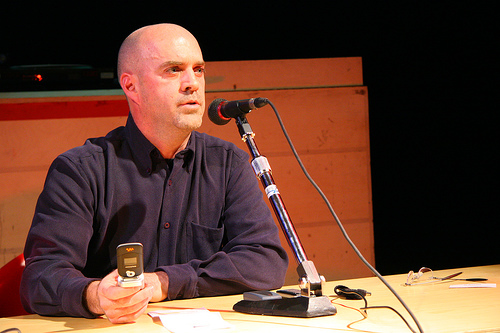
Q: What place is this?
A: It is a stage.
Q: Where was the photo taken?
A: It was taken at the stage.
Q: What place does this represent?
A: It represents the stage.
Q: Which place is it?
A: It is a stage.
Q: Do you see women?
A: No, there are no women.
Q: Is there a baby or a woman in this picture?
A: No, there are no women or babies.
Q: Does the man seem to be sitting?
A: Yes, the man is sitting.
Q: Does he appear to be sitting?
A: Yes, the man is sitting.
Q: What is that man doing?
A: The man is sitting.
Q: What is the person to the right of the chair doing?
A: The man is sitting.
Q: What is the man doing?
A: The man is sitting.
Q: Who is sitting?
A: The man is sitting.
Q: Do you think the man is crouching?
A: No, the man is sitting.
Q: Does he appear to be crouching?
A: No, the man is sitting.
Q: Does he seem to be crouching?
A: No, the man is sitting.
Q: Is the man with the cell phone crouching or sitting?
A: The man is sitting.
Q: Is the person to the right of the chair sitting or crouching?
A: The man is sitting.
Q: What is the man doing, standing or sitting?
A: The man is sitting.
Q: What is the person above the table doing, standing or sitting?
A: The man is sitting.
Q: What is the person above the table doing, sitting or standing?
A: The man is sitting.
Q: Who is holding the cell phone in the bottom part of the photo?
A: The man is holding the cell phone.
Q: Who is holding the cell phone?
A: The man is holding the cell phone.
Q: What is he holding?
A: The man is holding the mobile phone.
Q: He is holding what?
A: The man is holding the mobile phone.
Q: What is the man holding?
A: The man is holding the mobile phone.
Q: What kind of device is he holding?
A: The man is holding the mobile phone.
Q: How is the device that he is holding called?
A: The device is a cell phone.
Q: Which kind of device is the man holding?
A: The man is holding the mobile phone.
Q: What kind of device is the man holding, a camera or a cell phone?
A: The man is holding a cell phone.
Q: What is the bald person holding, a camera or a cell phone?
A: The man is holding a cell phone.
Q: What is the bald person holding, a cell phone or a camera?
A: The man is holding a cell phone.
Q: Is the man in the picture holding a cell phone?
A: Yes, the man is holding a cell phone.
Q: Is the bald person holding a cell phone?
A: Yes, the man is holding a cell phone.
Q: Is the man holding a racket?
A: No, the man is holding a cell phone.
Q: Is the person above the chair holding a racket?
A: No, the man is holding a cell phone.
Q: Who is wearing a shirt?
A: The man is wearing a shirt.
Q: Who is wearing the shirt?
A: The man is wearing a shirt.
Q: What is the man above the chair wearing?
A: The man is wearing a shirt.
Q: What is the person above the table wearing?
A: The man is wearing a shirt.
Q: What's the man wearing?
A: The man is wearing a shirt.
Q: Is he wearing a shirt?
A: Yes, the man is wearing a shirt.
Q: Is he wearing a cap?
A: No, the man is wearing a shirt.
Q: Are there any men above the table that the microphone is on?
A: Yes, there is a man above the table.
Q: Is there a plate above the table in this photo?
A: No, there is a man above the table.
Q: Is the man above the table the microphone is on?
A: Yes, the man is above the table.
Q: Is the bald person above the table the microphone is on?
A: Yes, the man is above the table.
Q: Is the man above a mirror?
A: No, the man is above the table.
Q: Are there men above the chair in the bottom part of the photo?
A: Yes, there is a man above the chair.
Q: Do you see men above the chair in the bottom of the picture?
A: Yes, there is a man above the chair.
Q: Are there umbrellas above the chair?
A: No, there is a man above the chair.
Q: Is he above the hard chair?
A: Yes, the man is above the chair.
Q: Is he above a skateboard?
A: No, the man is above the chair.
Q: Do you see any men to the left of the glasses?
A: Yes, there is a man to the left of the glasses.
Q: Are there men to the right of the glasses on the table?
A: No, the man is to the left of the glasses.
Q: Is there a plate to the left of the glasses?
A: No, there is a man to the left of the glasses.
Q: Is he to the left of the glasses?
A: Yes, the man is to the left of the glasses.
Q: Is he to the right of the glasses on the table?
A: No, the man is to the left of the glasses.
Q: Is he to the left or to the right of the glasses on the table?
A: The man is to the left of the glasses.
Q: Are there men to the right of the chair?
A: Yes, there is a man to the right of the chair.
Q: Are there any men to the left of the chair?
A: No, the man is to the right of the chair.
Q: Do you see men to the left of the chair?
A: No, the man is to the right of the chair.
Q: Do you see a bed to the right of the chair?
A: No, there is a man to the right of the chair.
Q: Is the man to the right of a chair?
A: Yes, the man is to the right of a chair.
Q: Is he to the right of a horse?
A: No, the man is to the right of a chair.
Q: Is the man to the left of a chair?
A: No, the man is to the right of a chair.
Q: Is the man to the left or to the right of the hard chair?
A: The man is to the right of the chair.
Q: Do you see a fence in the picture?
A: No, there are no fences.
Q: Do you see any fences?
A: No, there are no fences.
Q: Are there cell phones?
A: Yes, there is a cell phone.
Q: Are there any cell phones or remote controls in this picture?
A: Yes, there is a cell phone.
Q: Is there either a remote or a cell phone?
A: Yes, there is a cell phone.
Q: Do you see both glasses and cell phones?
A: Yes, there are both a cell phone and glasses.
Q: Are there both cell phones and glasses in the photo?
A: Yes, there are both a cell phone and glasses.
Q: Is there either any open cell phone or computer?
A: Yes, there is an open cell phone.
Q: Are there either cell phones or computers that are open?
A: Yes, the cell phone is open.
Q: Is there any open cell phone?
A: Yes, there is an open cell phone.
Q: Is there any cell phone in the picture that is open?
A: Yes, there is a cell phone that is open.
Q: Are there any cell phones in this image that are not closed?
A: Yes, there is a open cell phone.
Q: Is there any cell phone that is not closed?
A: Yes, there is a open cell phone.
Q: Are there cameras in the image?
A: No, there are no cameras.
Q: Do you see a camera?
A: No, there are no cameras.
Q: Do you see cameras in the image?
A: No, there are no cameras.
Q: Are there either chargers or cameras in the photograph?
A: No, there are no cameras or chargers.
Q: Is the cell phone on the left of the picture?
A: Yes, the cell phone is on the left of the image.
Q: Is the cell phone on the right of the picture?
A: No, the cell phone is on the left of the image.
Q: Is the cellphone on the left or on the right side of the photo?
A: The cellphone is on the left of the image.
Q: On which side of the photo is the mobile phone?
A: The mobile phone is on the left of the image.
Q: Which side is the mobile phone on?
A: The mobile phone is on the left of the image.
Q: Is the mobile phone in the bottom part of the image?
A: Yes, the mobile phone is in the bottom of the image.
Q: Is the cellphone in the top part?
A: No, the cellphone is in the bottom of the image.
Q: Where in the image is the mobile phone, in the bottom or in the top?
A: The mobile phone is in the bottom of the image.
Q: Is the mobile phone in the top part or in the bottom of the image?
A: The mobile phone is in the bottom of the image.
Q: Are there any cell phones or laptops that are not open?
A: No, there is a cell phone but it is open.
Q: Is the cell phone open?
A: Yes, the cell phone is open.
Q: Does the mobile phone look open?
A: Yes, the mobile phone is open.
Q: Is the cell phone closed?
A: No, the cell phone is open.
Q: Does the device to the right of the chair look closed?
A: No, the mobile phone is open.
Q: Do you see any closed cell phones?
A: No, there is a cell phone but it is open.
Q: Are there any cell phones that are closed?
A: No, there is a cell phone but it is open.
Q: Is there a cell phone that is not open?
A: No, there is a cell phone but it is open.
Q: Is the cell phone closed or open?
A: The cell phone is open.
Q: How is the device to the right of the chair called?
A: The device is a cell phone.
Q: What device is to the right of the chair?
A: The device is a cell phone.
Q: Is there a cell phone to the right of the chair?
A: Yes, there is a cell phone to the right of the chair.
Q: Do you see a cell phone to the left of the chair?
A: No, the cell phone is to the right of the chair.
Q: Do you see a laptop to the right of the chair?
A: No, there is a cell phone to the right of the chair.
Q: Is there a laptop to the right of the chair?
A: No, there is a cell phone to the right of the chair.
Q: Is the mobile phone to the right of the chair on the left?
A: Yes, the mobile phone is to the right of the chair.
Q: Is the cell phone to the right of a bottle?
A: No, the cell phone is to the right of the chair.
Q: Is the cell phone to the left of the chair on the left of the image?
A: No, the cell phone is to the right of the chair.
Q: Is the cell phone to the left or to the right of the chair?
A: The cell phone is to the right of the chair.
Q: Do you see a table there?
A: Yes, there is a table.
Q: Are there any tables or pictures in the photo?
A: Yes, there is a table.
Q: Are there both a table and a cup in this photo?
A: No, there is a table but no cups.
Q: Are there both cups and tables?
A: No, there is a table but no cups.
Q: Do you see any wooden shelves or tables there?
A: Yes, there is a wood table.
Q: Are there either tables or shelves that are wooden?
A: Yes, the table is wooden.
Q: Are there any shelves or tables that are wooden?
A: Yes, the table is wooden.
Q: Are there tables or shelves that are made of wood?
A: Yes, the table is made of wood.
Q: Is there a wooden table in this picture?
A: Yes, there is a wood table.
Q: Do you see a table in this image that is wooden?
A: Yes, there is a table that is wooden.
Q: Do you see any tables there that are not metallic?
A: Yes, there is a wooden table.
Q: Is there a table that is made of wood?
A: Yes, there is a table that is made of wood.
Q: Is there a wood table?
A: Yes, there is a table that is made of wood.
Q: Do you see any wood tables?
A: Yes, there is a table that is made of wood.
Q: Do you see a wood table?
A: Yes, there is a table that is made of wood.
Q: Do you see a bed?
A: No, there are no beds.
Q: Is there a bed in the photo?
A: No, there are no beds.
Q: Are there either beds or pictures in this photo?
A: No, there are no beds or pictures.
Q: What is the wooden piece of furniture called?
A: The piece of furniture is a table.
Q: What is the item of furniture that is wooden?
A: The piece of furniture is a table.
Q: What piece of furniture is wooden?
A: The piece of furniture is a table.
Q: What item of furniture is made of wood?
A: The piece of furniture is a table.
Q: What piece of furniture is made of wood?
A: The piece of furniture is a table.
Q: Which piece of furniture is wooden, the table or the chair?
A: The table is wooden.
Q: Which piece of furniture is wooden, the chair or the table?
A: The table is wooden.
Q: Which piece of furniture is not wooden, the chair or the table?
A: The chair is not wooden.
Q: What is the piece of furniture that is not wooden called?
A: The piece of furniture is a chair.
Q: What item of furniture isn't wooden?
A: The piece of furniture is a chair.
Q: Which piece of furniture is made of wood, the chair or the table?
A: The table is made of wood.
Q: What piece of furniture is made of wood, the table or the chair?
A: The table is made of wood.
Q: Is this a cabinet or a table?
A: This is a table.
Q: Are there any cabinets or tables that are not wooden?
A: No, there is a table but it is wooden.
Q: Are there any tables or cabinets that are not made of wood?
A: No, there is a table but it is made of wood.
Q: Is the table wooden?
A: Yes, the table is wooden.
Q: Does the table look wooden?
A: Yes, the table is wooden.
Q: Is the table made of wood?
A: Yes, the table is made of wood.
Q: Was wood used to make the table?
A: Yes, the table is made of wood.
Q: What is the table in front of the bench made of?
A: The table is made of wood.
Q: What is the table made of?
A: The table is made of wood.